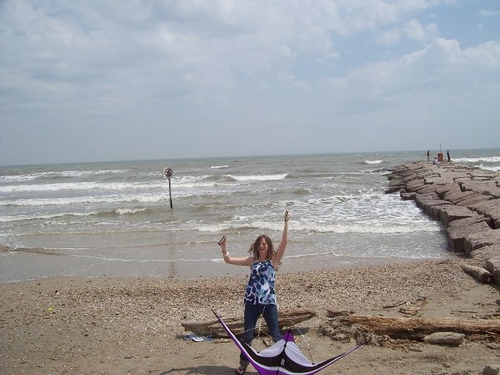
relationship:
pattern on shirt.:
[243, 258, 278, 306] [249, 271, 274, 297]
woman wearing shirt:
[218, 210, 289, 374] [247, 255, 276, 308]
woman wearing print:
[218, 210, 289, 374] [249, 267, 271, 300]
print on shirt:
[249, 267, 271, 300] [247, 255, 276, 308]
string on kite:
[243, 324, 270, 338] [195, 315, 340, 367]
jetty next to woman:
[375, 137, 495, 312] [218, 210, 289, 374]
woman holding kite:
[218, 210, 289, 374] [214, 309, 368, 374]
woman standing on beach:
[218, 210, 289, 374] [0, 237, 500, 372]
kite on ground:
[216, 309, 363, 369] [200, 348, 251, 372]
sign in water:
[162, 166, 174, 178] [1, 158, 368, 233]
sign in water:
[162, 166, 174, 209] [1, 158, 368, 233]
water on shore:
[5, 164, 423, 271] [0, 232, 500, 372]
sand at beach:
[0, 263, 499, 373] [165, 270, 339, 370]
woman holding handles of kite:
[218, 210, 289, 374] [214, 309, 368, 374]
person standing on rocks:
[444, 147, 452, 164] [395, 163, 472, 193]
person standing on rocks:
[422, 150, 432, 165] [395, 163, 472, 193]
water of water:
[0, 149, 499, 284] [0, 149, 499, 284]